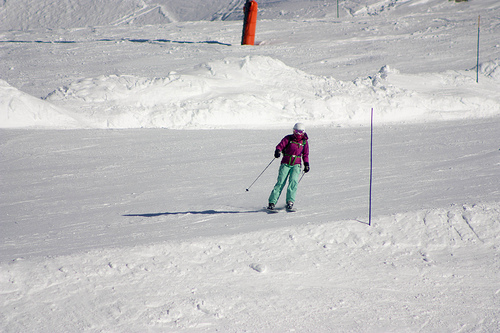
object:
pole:
[241, 0, 257, 45]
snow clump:
[0, 55, 498, 125]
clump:
[377, 62, 401, 76]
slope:
[3, 1, 498, 331]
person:
[262, 120, 313, 215]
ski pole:
[241, 150, 281, 195]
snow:
[0, 1, 496, 330]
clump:
[1, 55, 498, 129]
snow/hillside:
[16, 3, 202, 50]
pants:
[267, 162, 303, 202]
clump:
[7, 250, 24, 262]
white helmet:
[290, 120, 307, 136]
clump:
[205, 65, 335, 114]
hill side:
[50, 21, 497, 317]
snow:
[150, 287, 237, 327]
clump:
[105, 260, 118, 272]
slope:
[6, 197, 499, 328]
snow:
[122, 236, 305, 291]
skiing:
[220, 102, 370, 229]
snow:
[395, 180, 499, 282]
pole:
[367, 102, 376, 224]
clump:
[247, 259, 274, 273]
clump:
[215, 241, 224, 251]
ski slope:
[1, 0, 495, 331]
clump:
[391, 192, 491, 258]